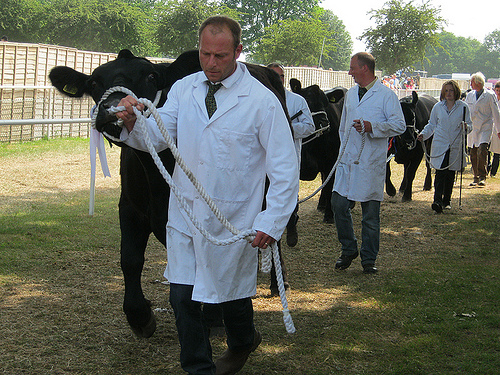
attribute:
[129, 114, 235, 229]
rope — white, holding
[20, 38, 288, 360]
cow — black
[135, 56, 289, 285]
jacket — white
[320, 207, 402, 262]
jeans — blue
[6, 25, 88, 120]
fence — wooden, long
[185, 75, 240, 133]
tie — black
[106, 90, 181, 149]
man — caucasian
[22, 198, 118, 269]
grass — green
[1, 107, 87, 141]
rail — white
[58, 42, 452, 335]
line — walking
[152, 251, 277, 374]
man — caucasian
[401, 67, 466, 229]
woman — standing, holding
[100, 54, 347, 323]
gown — white